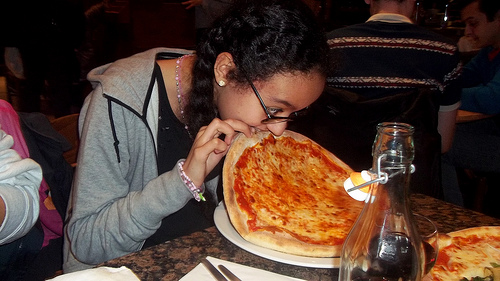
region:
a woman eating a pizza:
[33, 37, 451, 277]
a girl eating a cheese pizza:
[64, 33, 496, 271]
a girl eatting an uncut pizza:
[65, 36, 394, 277]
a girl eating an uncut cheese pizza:
[119, 12, 466, 254]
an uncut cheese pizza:
[212, 118, 365, 264]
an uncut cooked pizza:
[202, 101, 429, 279]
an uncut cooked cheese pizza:
[192, 123, 439, 278]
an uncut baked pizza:
[232, 107, 397, 279]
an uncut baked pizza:
[196, 84, 494, 279]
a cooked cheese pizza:
[235, 108, 450, 273]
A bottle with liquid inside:
[340, 120, 422, 279]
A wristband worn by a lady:
[175, 160, 207, 201]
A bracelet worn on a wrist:
[176, 159, 205, 201]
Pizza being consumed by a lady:
[221, 130, 391, 256]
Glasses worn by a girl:
[248, 73, 296, 123]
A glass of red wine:
[380, 214, 436, 278]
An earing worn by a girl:
[216, 77, 221, 83]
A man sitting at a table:
[322, 1, 459, 151]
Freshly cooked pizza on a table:
[417, 226, 498, 279]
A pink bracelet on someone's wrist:
[176, 158, 203, 200]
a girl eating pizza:
[56, 9, 395, 271]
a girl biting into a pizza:
[215, 73, 323, 174]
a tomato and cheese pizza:
[216, 136, 376, 270]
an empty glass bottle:
[340, 116, 430, 277]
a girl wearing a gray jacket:
[58, 15, 335, 272]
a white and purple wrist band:
[171, 150, 205, 217]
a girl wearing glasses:
[216, 48, 321, 151]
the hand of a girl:
[178, 110, 253, 198]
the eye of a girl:
[260, 103, 279, 119]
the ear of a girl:
[213, 49, 236, 88]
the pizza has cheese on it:
[219, 117, 391, 271]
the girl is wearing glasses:
[246, 75, 303, 131]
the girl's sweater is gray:
[65, 41, 196, 270]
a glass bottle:
[338, 112, 428, 279]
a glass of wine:
[373, 205, 439, 279]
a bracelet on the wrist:
[172, 153, 207, 204]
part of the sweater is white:
[1, 123, 45, 245]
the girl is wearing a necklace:
[164, 51, 211, 148]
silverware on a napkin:
[180, 245, 308, 280]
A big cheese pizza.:
[221, 130, 391, 258]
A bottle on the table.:
[337, 119, 424, 279]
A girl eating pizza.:
[62, 5, 333, 270]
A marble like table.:
[91, 191, 497, 278]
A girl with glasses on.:
[61, 4, 333, 276]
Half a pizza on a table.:
[418, 221, 497, 279]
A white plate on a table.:
[212, 198, 339, 271]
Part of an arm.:
[0, 128, 42, 246]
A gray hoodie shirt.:
[61, 45, 219, 272]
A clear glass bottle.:
[336, 120, 426, 279]